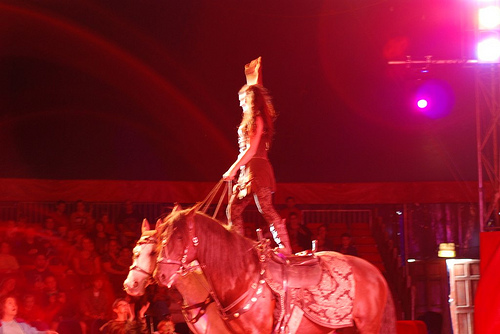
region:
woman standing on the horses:
[112, 34, 331, 314]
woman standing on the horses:
[131, 49, 351, 329]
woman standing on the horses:
[96, 19, 356, 331]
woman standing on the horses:
[116, 39, 350, 329]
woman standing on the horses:
[103, 20, 388, 332]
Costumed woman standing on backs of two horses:
[122, 54, 397, 332]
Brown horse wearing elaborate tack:
[151, 202, 396, 332]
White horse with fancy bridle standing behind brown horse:
[122, 216, 230, 331]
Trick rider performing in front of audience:
[223, 53, 292, 255]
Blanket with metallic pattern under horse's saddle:
[293, 249, 355, 327]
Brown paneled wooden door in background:
[444, 256, 483, 332]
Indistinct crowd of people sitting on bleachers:
[1, 196, 360, 332]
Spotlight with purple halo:
[412, 77, 457, 119]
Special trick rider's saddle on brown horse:
[256, 227, 323, 332]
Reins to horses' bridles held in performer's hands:
[196, 175, 233, 219]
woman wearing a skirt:
[215, 46, 298, 246]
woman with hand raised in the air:
[201, 51, 317, 243]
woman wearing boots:
[208, 60, 310, 245]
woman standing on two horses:
[220, 60, 301, 247]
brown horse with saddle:
[151, 198, 401, 316]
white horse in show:
[122, 213, 214, 325]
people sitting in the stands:
[10, 195, 342, 318]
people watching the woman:
[8, 195, 325, 323]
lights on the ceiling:
[400, 64, 445, 114]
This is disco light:
[395, 80, 441, 132]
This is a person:
[212, 47, 303, 278]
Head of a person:
[231, 78, 282, 120]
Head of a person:
[86, 275, 113, 304]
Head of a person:
[107, 293, 143, 328]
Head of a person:
[1, 291, 25, 322]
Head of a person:
[41, 268, 64, 295]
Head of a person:
[90, 215, 110, 235]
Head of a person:
[97, 209, 109, 228]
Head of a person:
[120, 200, 140, 218]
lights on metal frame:
[473, 1, 498, 233]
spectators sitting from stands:
[0, 194, 397, 331]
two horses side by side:
[123, 206, 395, 331]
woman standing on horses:
[123, 57, 392, 332]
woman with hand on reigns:
[202, 56, 287, 251]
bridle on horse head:
[155, 209, 197, 286]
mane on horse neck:
[169, 208, 245, 279]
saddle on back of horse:
[261, 248, 320, 286]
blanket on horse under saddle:
[262, 250, 354, 327]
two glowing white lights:
[475, 4, 498, 62]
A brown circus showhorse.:
[150, 203, 398, 331]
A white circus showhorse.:
[119, 215, 231, 332]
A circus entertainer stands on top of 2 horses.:
[215, 55, 297, 256]